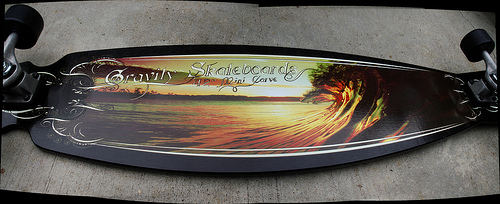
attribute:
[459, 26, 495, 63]
wheel — upside down, black, on right, visable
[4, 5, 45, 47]
wheel — upside down, black, to left, visable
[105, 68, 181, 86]
gravity word — writing, white, lettering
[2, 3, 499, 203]
concrete — grey, edged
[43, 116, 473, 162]
lower white border — line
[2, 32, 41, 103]
metal — holder, silver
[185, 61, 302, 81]
skateboard word — script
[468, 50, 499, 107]
holder — metal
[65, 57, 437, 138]
design — at sunset, of water, orange, yellow, green, sunny, setting sun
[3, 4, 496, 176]
skateboard — upside down, black, artfully designed, made of wood, wooden, wood